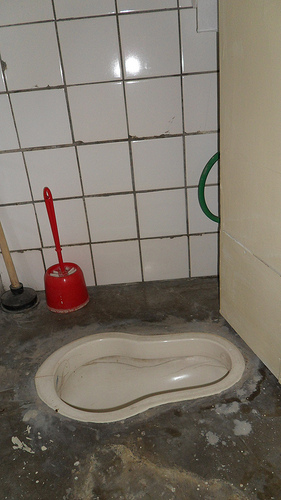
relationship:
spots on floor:
[5, 432, 46, 457] [1, 280, 280, 499]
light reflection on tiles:
[108, 53, 152, 85] [1, 1, 217, 280]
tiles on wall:
[1, 1, 217, 280] [3, 0, 280, 305]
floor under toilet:
[1, 280, 280, 499] [32, 329, 248, 424]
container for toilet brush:
[43, 266, 92, 314] [40, 186, 81, 281]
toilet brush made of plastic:
[40, 186, 81, 281] [49, 193, 52, 211]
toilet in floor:
[32, 329, 248, 424] [1, 280, 280, 499]